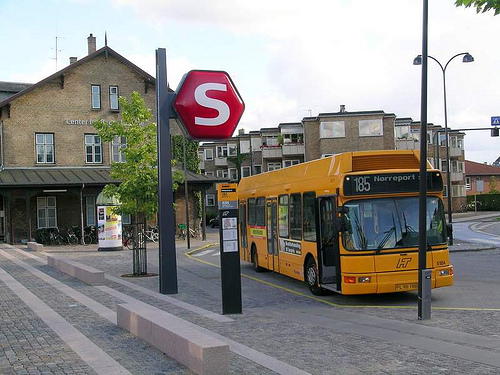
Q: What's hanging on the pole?
A: Red and white sign.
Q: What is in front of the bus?
A: Pole.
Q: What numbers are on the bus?
A: 185.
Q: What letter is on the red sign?
A: S.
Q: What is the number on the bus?
A: 185.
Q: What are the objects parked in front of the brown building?
A: Bicycles.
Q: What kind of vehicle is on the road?
A: Bus.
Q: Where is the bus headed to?
A: Norreport.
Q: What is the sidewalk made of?
A: Paving stones.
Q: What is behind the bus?
A: Buildings.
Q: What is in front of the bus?
A: Pole.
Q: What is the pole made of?
A: Metal.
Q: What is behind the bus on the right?
A: Lamppost.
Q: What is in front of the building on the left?
A: Tree.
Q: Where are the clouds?
A: Sky.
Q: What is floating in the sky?
A: Clouds.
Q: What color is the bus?
A: Yellow.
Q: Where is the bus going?
A: Harreport.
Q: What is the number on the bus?
A: 185.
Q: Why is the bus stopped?
A: It's at a bus stop.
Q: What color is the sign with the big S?
A: Red.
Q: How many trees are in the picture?
A: Two.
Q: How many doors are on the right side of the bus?
A: Three.